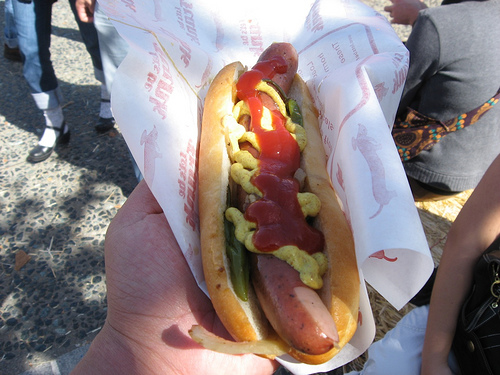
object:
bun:
[198, 42, 363, 366]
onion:
[187, 323, 291, 358]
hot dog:
[239, 41, 341, 353]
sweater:
[400, 0, 498, 195]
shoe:
[28, 113, 72, 163]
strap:
[42, 125, 65, 132]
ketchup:
[236, 58, 325, 255]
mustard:
[225, 81, 328, 288]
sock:
[37, 104, 70, 149]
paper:
[89, 1, 433, 375]